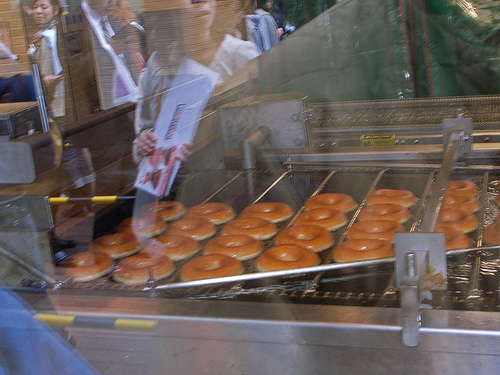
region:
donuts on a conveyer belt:
[50, 162, 472, 275]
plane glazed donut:
[108, 241, 171, 287]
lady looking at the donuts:
[129, 1, 241, 160]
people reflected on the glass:
[11, 2, 250, 234]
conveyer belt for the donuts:
[20, 154, 495, 311]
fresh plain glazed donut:
[252, 239, 322, 277]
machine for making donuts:
[2, 107, 487, 336]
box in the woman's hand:
[137, 59, 222, 194]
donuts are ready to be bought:
[62, 166, 484, 296]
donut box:
[122, 49, 228, 201]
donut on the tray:
[267, 244, 321, 268]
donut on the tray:
[278, 225, 328, 246]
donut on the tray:
[296, 208, 340, 227]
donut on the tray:
[308, 189, 349, 213]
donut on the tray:
[243, 203, 288, 215]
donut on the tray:
[228, 218, 272, 236]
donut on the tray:
[207, 235, 254, 255]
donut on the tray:
[186, 254, 237, 273]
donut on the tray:
[189, 196, 229, 222]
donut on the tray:
[172, 219, 217, 237]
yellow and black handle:
[22, 305, 169, 334]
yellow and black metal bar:
[37, 189, 167, 210]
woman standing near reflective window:
[111, 0, 302, 371]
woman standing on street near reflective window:
[16, 1, 103, 221]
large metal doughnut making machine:
[0, 82, 498, 373]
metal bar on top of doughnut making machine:
[385, 103, 477, 352]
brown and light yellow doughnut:
[254, 242, 326, 281]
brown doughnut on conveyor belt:
[332, 232, 395, 271]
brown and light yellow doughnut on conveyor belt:
[235, 198, 297, 225]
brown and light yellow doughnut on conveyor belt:
[52, 246, 117, 284]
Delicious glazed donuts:
[91, 185, 472, 279]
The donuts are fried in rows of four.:
[127, 186, 286, 282]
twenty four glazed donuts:
[62, 180, 491, 280]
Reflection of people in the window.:
[21, 10, 295, 197]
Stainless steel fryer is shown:
[91, 280, 488, 373]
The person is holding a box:
[121, 5, 253, 197]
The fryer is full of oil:
[230, 250, 430, 330]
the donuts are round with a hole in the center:
[250, 231, 320, 281]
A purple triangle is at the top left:
[82, 53, 154, 106]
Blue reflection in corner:
[0, 253, 115, 370]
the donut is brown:
[113, 251, 169, 290]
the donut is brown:
[176, 233, 221, 288]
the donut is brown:
[240, 228, 332, 300]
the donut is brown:
[336, 232, 394, 271]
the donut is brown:
[341, 217, 417, 257]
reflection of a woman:
[127, 1, 301, 226]